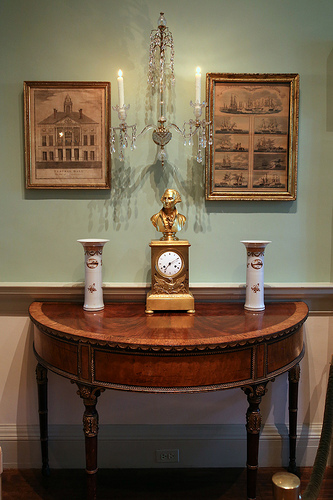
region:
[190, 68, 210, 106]
a candle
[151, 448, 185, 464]
an electrical plug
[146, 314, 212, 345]
a wooden table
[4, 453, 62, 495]
a shadow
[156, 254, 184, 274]
a clock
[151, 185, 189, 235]
a statue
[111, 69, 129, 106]
the candle is white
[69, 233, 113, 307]
a vase on the table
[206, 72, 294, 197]
picture on the wall is gold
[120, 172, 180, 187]
shadow on the wall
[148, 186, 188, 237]
bust on top of a clock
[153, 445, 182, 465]
electrical outlet in the wall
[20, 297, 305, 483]
wooden semicircular table against the wall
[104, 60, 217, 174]
two candles on the wall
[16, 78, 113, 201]
picture of a building on the wall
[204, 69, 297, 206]
picture depicting various ships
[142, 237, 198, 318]
clock on the table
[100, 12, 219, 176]
crystal candle holder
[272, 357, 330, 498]
ropes and post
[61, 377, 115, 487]
intricately carved table leg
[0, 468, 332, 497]
dark brown wooden flooring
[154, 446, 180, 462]
white plastic power outlet cover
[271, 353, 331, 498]
metal pole and velvet rope boundary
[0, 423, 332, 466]
white base board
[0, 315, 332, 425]
pale peach painted wall section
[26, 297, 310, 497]
highly polished wooden side table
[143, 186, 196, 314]
gold clock with a bust of George Washington on it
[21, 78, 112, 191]
framed drawing of a house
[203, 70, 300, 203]
framed drawing of ships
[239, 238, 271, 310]
white vase with gold decorations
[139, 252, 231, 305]
This is a clock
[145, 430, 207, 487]
This is an outlet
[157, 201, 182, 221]
This is george washington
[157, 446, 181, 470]
The outlet is white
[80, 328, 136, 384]
This is a wooden desk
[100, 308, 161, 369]
The desk is dark brown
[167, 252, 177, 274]
The clock is white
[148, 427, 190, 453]
This is crown moulding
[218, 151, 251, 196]
This is a painting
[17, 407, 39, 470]
This is very green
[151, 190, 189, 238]
gold bust of George Washington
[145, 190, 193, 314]
gold clock with president Washington on top.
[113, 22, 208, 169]
crystal wall sconce with two candles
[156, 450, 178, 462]
power outlet near the floor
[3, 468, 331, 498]
a wood floor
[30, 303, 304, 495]
small side table against the wall.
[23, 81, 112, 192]
framed picture of a building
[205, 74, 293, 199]
framed picture of several ships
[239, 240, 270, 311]
the white vase on the right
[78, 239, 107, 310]
the white vase on the left